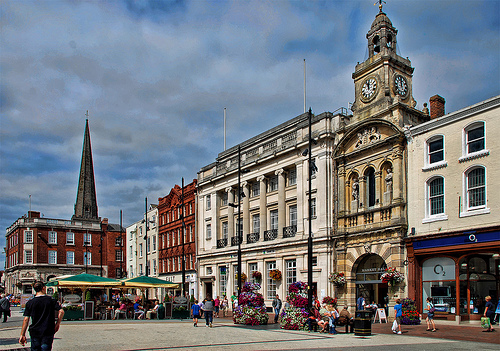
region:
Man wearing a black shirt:
[17, 276, 66, 350]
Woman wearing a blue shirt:
[392, 293, 407, 338]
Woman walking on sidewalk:
[422, 295, 442, 335]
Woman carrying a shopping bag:
[476, 291, 496, 333]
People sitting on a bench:
[300, 299, 344, 333]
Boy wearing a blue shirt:
[187, 300, 202, 327]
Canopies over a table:
[47, 264, 180, 321]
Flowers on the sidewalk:
[278, 276, 325, 337]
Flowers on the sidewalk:
[229, 276, 271, 331]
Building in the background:
[2, 194, 133, 310]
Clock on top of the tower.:
[356, 70, 382, 112]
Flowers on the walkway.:
[229, 279, 276, 341]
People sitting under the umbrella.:
[124, 268, 177, 335]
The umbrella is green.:
[114, 263, 179, 292]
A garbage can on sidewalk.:
[340, 295, 382, 339]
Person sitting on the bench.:
[321, 302, 350, 329]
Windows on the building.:
[200, 185, 297, 233]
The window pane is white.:
[410, 179, 450, 224]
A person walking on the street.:
[18, 267, 61, 344]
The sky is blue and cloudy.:
[36, 96, 173, 166]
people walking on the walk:
[391, 295, 499, 335]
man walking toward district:
[12, 277, 73, 345]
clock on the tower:
[358, 74, 381, 104]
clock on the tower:
[392, 69, 409, 102]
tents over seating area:
[46, 271, 175, 289]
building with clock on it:
[331, 4, 422, 334]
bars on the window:
[210, 229, 307, 252]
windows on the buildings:
[45, 233, 98, 264]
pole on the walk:
[226, 134, 263, 331]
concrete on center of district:
[94, 322, 304, 349]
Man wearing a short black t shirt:
[19, 278, 63, 340]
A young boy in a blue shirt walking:
[183, 293, 206, 327]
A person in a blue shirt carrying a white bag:
[386, 297, 410, 335]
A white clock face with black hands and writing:
[361, 74, 376, 102]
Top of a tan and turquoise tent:
[56, 269, 125, 290]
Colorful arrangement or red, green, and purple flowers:
[231, 277, 268, 326]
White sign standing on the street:
[371, 303, 388, 325]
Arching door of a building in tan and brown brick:
[339, 245, 396, 267]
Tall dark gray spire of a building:
[71, 107, 103, 227]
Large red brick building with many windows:
[155, 188, 197, 268]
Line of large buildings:
[0, 0, 498, 344]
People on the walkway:
[0, 288, 499, 350]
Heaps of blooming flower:
[230, 268, 421, 330]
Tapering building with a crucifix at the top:
[68, 108, 108, 222]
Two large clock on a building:
[356, 73, 413, 103]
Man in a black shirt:
[18, 277, 65, 348]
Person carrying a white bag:
[389, 298, 406, 336]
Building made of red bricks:
[4, 211, 129, 305]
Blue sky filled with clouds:
[1, 1, 499, 271]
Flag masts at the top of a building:
[219, 52, 313, 154]